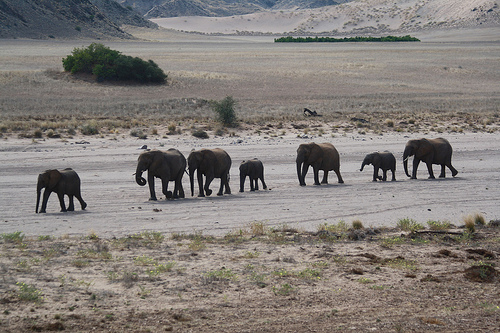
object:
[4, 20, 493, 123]
desert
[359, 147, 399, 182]
elephant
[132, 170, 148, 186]
trunk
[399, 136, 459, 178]
elephant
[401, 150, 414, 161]
tusk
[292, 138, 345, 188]
elephant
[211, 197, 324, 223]
ground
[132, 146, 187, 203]
elephant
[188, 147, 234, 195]
elephant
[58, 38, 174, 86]
bush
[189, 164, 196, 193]
tail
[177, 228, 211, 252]
grass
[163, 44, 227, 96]
sand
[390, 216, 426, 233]
grass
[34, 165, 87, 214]
elephant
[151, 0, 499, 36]
mountains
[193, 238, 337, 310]
ground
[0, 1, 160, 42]
hillside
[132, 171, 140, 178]
tusk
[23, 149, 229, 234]
road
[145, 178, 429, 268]
road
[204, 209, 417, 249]
road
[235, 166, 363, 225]
road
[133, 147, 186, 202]
elephants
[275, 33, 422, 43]
bush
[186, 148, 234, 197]
elephants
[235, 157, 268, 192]
elephant